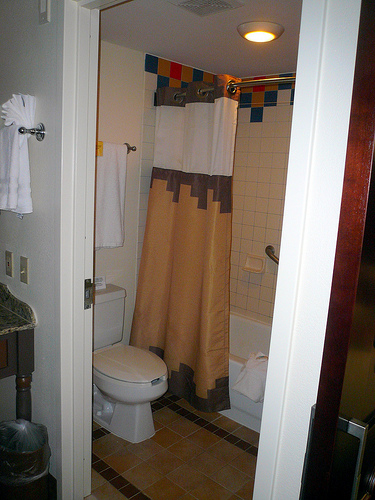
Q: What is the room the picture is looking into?
A: The bathroom.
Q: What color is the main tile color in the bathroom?
A: White.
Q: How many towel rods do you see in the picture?
A: 2.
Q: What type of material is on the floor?
A: Tiles.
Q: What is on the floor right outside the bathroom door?
A: Trash can.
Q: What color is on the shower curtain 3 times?
A: Brown.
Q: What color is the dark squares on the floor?
A: Brown.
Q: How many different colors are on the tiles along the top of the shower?
A: 3.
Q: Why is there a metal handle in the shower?
A: To keep people from falling.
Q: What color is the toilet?
A: White.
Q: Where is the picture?
A: Bathroom.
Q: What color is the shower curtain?
A: Brown.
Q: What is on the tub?
A: A towel.